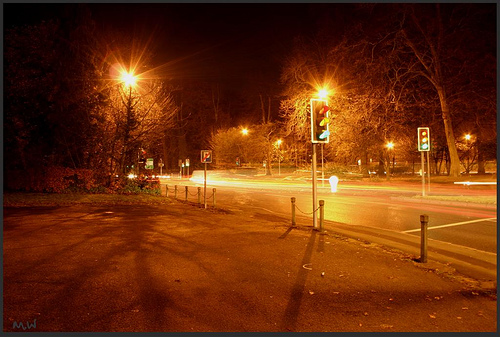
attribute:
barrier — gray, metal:
[415, 209, 431, 266]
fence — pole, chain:
[165, 182, 217, 208]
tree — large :
[382, 12, 472, 177]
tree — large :
[272, 24, 433, 166]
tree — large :
[87, 46, 182, 167]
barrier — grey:
[418, 212, 427, 258]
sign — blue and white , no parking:
[201, 148, 212, 210]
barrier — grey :
[308, 190, 328, 231]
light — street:
[85, 50, 194, 113]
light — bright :
[91, 63, 208, 205]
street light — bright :
[308, 86, 331, 191]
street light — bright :
[115, 62, 138, 180]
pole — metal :
[308, 141, 325, 236]